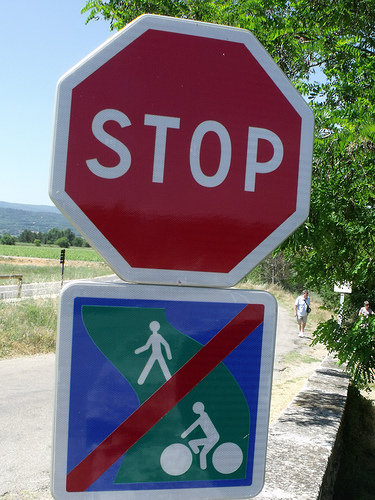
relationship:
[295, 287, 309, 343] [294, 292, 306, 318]
person standing wearing a white shirt